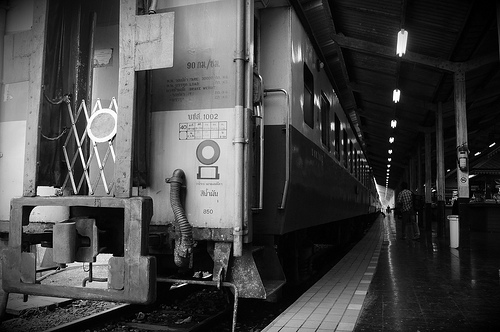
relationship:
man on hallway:
[397, 181, 422, 240] [340, 257, 474, 305]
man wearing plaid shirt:
[397, 181, 422, 240] [399, 190, 413, 211]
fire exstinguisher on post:
[456, 142, 469, 172] [453, 59, 472, 294]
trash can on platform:
[446, 214, 459, 248] [211, 214, 497, 330]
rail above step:
[255, 86, 290, 209] [237, 250, 288, 300]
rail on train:
[255, 86, 290, 209] [1, 0, 387, 330]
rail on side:
[255, 86, 290, 209] [236, 4, 376, 239]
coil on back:
[165, 169, 199, 269] [8, 12, 263, 320]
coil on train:
[165, 169, 199, 269] [4, 4, 391, 299]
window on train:
[298, 61, 329, 137] [5, 8, 412, 317]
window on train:
[291, 91, 369, 148] [82, 13, 493, 274]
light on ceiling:
[384, 84, 413, 109] [284, 8, 474, 196]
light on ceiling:
[381, 85, 403, 106] [276, 4, 484, 196]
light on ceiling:
[385, 145, 394, 155] [296, 0, 498, 205]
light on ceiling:
[387, 149, 393, 156] [312, 2, 497, 213]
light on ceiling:
[387, 148, 395, 155] [297, 4, 498, 186]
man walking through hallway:
[384, 174, 425, 246] [321, 154, 408, 304]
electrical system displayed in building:
[142, 102, 256, 269] [240, 9, 482, 329]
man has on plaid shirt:
[397, 181, 422, 240] [394, 187, 417, 210]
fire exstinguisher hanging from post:
[456, 145, 469, 170] [452, 70, 469, 197]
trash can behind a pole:
[448, 215, 460, 250] [452, 62, 472, 284]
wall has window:
[283, 11, 372, 207] [297, 62, 316, 132]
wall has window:
[283, 11, 372, 207] [317, 87, 332, 151]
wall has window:
[283, 11, 372, 207] [334, 113, 343, 163]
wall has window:
[283, 11, 372, 207] [340, 124, 350, 174]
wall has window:
[283, 11, 372, 207] [353, 145, 363, 182]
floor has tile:
[290, 286, 497, 329] [349, 302, 362, 312]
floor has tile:
[290, 286, 497, 329] [354, 285, 369, 298]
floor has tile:
[290, 286, 497, 329] [360, 275, 372, 287]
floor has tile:
[290, 286, 497, 329] [366, 260, 376, 272]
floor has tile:
[290, 286, 497, 329] [363, 270, 375, 280]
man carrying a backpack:
[397, 181, 422, 240] [410, 184, 429, 211]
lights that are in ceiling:
[379, 20, 411, 206] [374, 11, 416, 210]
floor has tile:
[253, 209, 498, 329] [324, 309, 343, 323]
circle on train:
[194, 139, 220, 165] [267, 82, 367, 228]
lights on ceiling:
[380, 25, 422, 110] [328, 6, 434, 207]